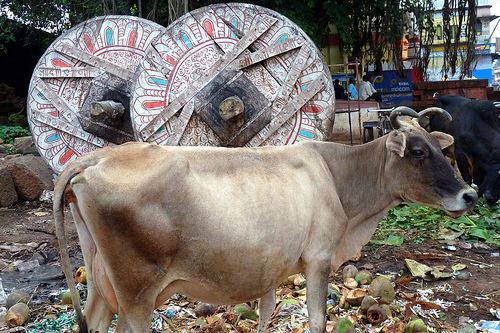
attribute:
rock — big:
[2, 150, 52, 209]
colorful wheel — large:
[128, 2, 334, 146]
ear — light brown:
[381, 122, 407, 162]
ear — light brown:
[425, 124, 459, 152]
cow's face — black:
[385, 124, 479, 221]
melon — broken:
[367, 274, 397, 304]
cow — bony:
[42, 98, 474, 325]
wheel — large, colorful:
[129, 0, 336, 148]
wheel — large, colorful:
[23, 12, 167, 173]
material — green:
[379, 206, 484, 245]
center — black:
[196, 80, 273, 140]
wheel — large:
[132, 9, 335, 156]